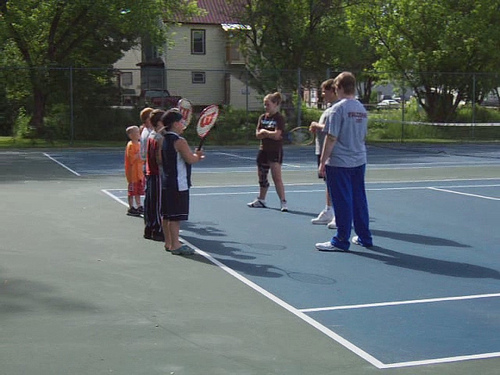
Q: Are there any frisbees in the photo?
A: No, there are no frisbees.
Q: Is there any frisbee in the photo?
A: No, there are no frisbees.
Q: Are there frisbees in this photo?
A: No, there are no frisbees.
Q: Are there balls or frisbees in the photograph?
A: No, there are no frisbees or balls.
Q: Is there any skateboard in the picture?
A: No, there are no skateboards.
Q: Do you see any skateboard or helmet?
A: No, there are no skateboards or helmets.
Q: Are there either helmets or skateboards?
A: No, there are no skateboards or helmets.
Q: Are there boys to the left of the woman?
A: Yes, there is a boy to the left of the woman.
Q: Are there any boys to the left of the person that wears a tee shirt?
A: Yes, there is a boy to the left of the woman.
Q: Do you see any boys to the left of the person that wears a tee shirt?
A: Yes, there is a boy to the left of the woman.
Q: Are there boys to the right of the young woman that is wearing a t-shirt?
A: No, the boy is to the left of the woman.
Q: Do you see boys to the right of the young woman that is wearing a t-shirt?
A: No, the boy is to the left of the woman.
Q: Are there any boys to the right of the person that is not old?
A: No, the boy is to the left of the woman.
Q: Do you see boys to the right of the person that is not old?
A: No, the boy is to the left of the woman.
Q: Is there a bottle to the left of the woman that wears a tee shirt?
A: No, there is a boy to the left of the woman.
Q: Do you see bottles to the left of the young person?
A: No, there is a boy to the left of the woman.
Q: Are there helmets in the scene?
A: No, there are no helmets.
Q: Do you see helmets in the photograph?
A: No, there are no helmets.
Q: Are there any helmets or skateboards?
A: No, there are no helmets or skateboards.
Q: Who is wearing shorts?
A: The boy is wearing shorts.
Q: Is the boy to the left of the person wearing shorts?
A: Yes, the boy is wearing shorts.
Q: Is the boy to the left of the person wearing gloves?
A: No, the boy is wearing shorts.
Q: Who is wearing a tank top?
A: The boy is wearing a tank top.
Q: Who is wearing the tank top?
A: The boy is wearing a tank top.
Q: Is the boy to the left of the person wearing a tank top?
A: Yes, the boy is wearing a tank top.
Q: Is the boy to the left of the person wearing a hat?
A: No, the boy is wearing a tank top.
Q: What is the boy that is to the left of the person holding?
A: The boy is holding the racket.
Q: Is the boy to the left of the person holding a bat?
A: No, the boy is holding the racket.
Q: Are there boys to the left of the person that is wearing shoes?
A: Yes, there is a boy to the left of the person.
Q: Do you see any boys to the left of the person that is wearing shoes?
A: Yes, there is a boy to the left of the person.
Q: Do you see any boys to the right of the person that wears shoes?
A: No, the boy is to the left of the person.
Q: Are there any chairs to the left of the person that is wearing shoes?
A: No, there is a boy to the left of the person.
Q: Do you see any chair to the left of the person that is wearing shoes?
A: No, there is a boy to the left of the person.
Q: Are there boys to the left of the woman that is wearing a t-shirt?
A: Yes, there is a boy to the left of the woman.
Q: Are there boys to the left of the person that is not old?
A: Yes, there is a boy to the left of the woman.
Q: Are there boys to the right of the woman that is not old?
A: No, the boy is to the left of the woman.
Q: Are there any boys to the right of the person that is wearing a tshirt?
A: No, the boy is to the left of the woman.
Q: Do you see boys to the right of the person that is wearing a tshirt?
A: No, the boy is to the left of the woman.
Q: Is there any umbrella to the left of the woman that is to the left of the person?
A: No, there is a boy to the left of the woman.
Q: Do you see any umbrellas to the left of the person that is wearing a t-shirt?
A: No, there is a boy to the left of the woman.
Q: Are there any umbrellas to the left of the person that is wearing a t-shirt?
A: No, there is a boy to the left of the woman.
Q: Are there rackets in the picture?
A: Yes, there is a racket.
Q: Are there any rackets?
A: Yes, there is a racket.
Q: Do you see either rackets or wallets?
A: Yes, there is a racket.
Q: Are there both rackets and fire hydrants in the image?
A: No, there is a racket but no fire hydrants.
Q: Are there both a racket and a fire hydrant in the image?
A: No, there is a racket but no fire hydrants.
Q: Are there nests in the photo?
A: No, there are no nests.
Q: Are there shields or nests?
A: No, there are no nests or shields.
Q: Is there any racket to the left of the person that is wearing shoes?
A: Yes, there is a racket to the left of the person.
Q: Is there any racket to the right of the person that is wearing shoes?
A: No, the racket is to the left of the person.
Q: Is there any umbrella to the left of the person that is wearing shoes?
A: No, there is a racket to the left of the person.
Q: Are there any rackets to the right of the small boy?
A: Yes, there is a racket to the right of the boy.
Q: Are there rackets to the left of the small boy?
A: No, the racket is to the right of the boy.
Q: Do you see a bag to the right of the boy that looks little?
A: No, there is a racket to the right of the boy.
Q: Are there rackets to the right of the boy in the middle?
A: Yes, there is a racket to the right of the boy.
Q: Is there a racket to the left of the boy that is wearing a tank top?
A: No, the racket is to the right of the boy.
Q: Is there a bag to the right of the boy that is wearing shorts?
A: No, there is a racket to the right of the boy.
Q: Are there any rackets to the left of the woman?
A: Yes, there is a racket to the left of the woman.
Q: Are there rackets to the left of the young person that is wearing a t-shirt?
A: Yes, there is a racket to the left of the woman.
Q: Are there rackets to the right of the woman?
A: No, the racket is to the left of the woman.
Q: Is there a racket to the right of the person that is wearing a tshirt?
A: No, the racket is to the left of the woman.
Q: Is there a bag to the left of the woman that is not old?
A: No, there is a racket to the left of the woman.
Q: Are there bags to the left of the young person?
A: No, there is a racket to the left of the woman.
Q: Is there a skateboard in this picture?
A: No, there are no skateboards.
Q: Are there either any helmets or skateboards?
A: No, there are no skateboards or helmets.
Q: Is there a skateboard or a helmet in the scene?
A: No, there are no skateboards or helmets.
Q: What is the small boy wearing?
A: The boy is wearing a shirt.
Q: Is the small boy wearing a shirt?
A: Yes, the boy is wearing a shirt.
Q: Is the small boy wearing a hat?
A: No, the boy is wearing a shirt.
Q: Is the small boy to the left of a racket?
A: Yes, the boy is to the left of a racket.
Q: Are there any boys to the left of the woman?
A: Yes, there is a boy to the left of the woman.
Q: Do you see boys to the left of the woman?
A: Yes, there is a boy to the left of the woman.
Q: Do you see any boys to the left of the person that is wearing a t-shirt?
A: Yes, there is a boy to the left of the woman.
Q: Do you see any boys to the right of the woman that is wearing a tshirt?
A: No, the boy is to the left of the woman.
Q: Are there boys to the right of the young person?
A: No, the boy is to the left of the woman.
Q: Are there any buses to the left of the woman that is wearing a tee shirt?
A: No, there is a boy to the left of the woman.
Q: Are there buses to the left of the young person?
A: No, there is a boy to the left of the woman.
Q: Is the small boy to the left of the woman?
A: Yes, the boy is to the left of the woman.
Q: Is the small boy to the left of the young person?
A: Yes, the boy is to the left of the woman.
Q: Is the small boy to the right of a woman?
A: No, the boy is to the left of a woman.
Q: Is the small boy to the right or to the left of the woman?
A: The boy is to the left of the woman.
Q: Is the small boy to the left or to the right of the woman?
A: The boy is to the left of the woman.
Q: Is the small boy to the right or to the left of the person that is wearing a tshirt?
A: The boy is to the left of the woman.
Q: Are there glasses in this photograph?
A: No, there are no glasses.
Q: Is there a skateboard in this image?
A: No, there are no skateboards.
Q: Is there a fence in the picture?
A: Yes, there is a fence.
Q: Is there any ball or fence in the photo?
A: Yes, there is a fence.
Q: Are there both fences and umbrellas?
A: No, there is a fence but no umbrellas.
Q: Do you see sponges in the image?
A: No, there are no sponges.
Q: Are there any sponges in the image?
A: No, there are no sponges.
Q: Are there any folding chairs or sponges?
A: No, there are no sponges or folding chairs.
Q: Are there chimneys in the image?
A: No, there are no chimneys.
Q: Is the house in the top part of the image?
A: Yes, the house is in the top of the image.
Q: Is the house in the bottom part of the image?
A: No, the house is in the top of the image.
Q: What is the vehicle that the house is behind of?
A: The vehicle is a truck.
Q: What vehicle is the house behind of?
A: The house is behind the truck.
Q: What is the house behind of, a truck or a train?
A: The house is behind a truck.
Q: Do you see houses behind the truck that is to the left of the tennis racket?
A: Yes, there is a house behind the truck.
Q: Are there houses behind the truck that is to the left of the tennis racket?
A: Yes, there is a house behind the truck.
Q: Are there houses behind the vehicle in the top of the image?
A: Yes, there is a house behind the truck.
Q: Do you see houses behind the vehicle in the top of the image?
A: Yes, there is a house behind the truck.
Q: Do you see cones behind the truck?
A: No, there is a house behind the truck.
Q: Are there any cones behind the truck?
A: No, there is a house behind the truck.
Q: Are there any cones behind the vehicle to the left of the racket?
A: No, there is a house behind the truck.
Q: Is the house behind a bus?
A: No, the house is behind the truck.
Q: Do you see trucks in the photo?
A: Yes, there is a truck.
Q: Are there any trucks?
A: Yes, there is a truck.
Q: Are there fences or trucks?
A: Yes, there is a truck.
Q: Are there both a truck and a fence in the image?
A: Yes, there are both a truck and a fence.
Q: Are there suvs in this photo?
A: No, there are no suvs.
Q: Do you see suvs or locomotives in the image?
A: No, there are no suvs or locomotives.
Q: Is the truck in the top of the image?
A: Yes, the truck is in the top of the image.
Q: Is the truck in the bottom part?
A: No, the truck is in the top of the image.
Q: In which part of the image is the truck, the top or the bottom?
A: The truck is in the top of the image.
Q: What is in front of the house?
A: The truck is in front of the house.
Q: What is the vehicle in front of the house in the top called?
A: The vehicle is a truck.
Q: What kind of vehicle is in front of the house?
A: The vehicle is a truck.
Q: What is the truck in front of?
A: The truck is in front of the house.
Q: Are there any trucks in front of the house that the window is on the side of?
A: Yes, there is a truck in front of the house.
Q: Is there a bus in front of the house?
A: No, there is a truck in front of the house.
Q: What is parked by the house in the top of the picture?
A: The truck is parked by the house.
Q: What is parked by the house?
A: The truck is parked by the house.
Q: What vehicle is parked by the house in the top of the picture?
A: The vehicle is a truck.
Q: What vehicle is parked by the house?
A: The vehicle is a truck.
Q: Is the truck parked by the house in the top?
A: Yes, the truck is parked by the house.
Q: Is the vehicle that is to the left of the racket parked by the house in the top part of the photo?
A: Yes, the truck is parked by the house.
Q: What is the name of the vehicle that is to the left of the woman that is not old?
A: The vehicle is a truck.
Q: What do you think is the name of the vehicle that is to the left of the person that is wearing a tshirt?
A: The vehicle is a truck.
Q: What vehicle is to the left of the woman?
A: The vehicle is a truck.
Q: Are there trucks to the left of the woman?
A: Yes, there is a truck to the left of the woman.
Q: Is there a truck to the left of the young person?
A: Yes, there is a truck to the left of the woman.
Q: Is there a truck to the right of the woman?
A: No, the truck is to the left of the woman.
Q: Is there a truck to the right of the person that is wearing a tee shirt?
A: No, the truck is to the left of the woman.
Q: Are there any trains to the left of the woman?
A: No, there is a truck to the left of the woman.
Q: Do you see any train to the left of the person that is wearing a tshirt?
A: No, there is a truck to the left of the woman.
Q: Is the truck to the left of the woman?
A: Yes, the truck is to the left of the woman.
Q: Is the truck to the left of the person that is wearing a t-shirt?
A: Yes, the truck is to the left of the woman.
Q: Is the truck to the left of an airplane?
A: No, the truck is to the left of the woman.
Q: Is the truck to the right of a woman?
A: No, the truck is to the left of a woman.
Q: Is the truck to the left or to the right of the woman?
A: The truck is to the left of the woman.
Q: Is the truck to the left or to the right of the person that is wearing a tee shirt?
A: The truck is to the left of the woman.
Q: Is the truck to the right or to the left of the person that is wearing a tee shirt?
A: The truck is to the left of the woman.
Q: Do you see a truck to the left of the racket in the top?
A: Yes, there is a truck to the left of the tennis racket.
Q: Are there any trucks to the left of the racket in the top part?
A: Yes, there is a truck to the left of the tennis racket.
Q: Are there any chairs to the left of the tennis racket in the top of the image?
A: No, there is a truck to the left of the racket.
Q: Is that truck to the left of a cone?
A: No, the truck is to the left of the racket.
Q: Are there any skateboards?
A: No, there are no skateboards.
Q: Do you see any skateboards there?
A: No, there are no skateboards.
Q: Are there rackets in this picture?
A: Yes, there is a racket.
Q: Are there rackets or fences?
A: Yes, there is a racket.